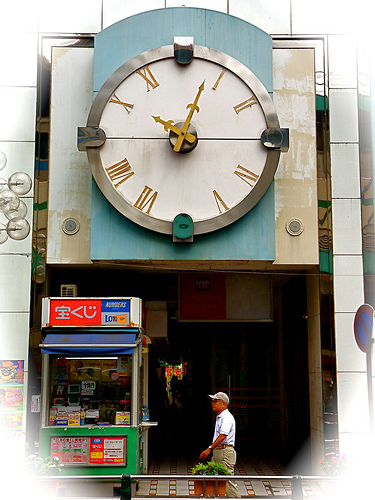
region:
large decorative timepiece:
[73, 31, 307, 252]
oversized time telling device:
[66, 25, 310, 248]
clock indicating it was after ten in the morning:
[69, 27, 304, 254]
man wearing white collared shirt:
[186, 383, 242, 498]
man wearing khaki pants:
[193, 383, 247, 496]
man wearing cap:
[191, 387, 253, 498]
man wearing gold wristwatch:
[189, 385, 239, 497]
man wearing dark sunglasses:
[196, 386, 257, 497]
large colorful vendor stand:
[27, 282, 163, 495]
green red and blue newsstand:
[28, 291, 159, 482]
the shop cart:
[37, 294, 151, 484]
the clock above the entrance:
[80, 37, 306, 251]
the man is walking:
[186, 372, 247, 459]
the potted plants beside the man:
[193, 454, 229, 475]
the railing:
[31, 470, 364, 488]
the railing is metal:
[64, 470, 345, 491]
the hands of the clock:
[140, 68, 225, 178]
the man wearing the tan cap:
[186, 372, 256, 475]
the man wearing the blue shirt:
[201, 408, 242, 451]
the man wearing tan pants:
[202, 444, 247, 495]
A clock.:
[84, 49, 279, 235]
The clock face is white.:
[80, 45, 291, 247]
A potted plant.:
[188, 458, 234, 495]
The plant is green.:
[186, 458, 235, 492]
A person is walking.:
[186, 377, 244, 476]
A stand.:
[36, 292, 157, 480]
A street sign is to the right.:
[338, 297, 373, 459]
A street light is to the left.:
[0, 138, 38, 273]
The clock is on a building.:
[39, 1, 360, 291]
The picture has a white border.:
[295, 398, 373, 498]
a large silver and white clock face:
[81, 39, 286, 250]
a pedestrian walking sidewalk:
[197, 386, 241, 495]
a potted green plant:
[191, 457, 231, 493]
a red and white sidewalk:
[147, 462, 325, 496]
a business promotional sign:
[45, 299, 131, 327]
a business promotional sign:
[49, 437, 126, 468]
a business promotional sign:
[0, 359, 24, 383]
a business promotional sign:
[0, 386, 23, 407]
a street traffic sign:
[347, 303, 371, 356]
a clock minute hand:
[173, 78, 208, 153]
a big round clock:
[60, 10, 309, 259]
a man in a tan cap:
[195, 387, 237, 498]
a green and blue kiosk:
[32, 290, 161, 484]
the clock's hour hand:
[149, 112, 202, 150]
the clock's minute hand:
[177, 82, 201, 157]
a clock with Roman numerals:
[60, 6, 328, 263]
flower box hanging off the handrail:
[190, 454, 226, 497]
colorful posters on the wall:
[1, 358, 28, 472]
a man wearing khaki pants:
[196, 384, 252, 498]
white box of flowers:
[19, 454, 65, 497]